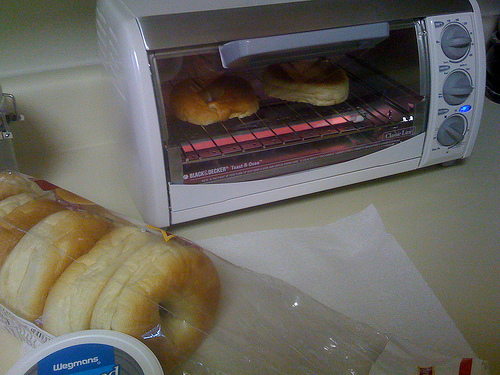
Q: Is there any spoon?
A: No, there are no spoons.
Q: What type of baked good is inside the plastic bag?
A: The food is a bagel.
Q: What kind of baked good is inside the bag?
A: The food is a bagel.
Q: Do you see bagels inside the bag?
A: Yes, there is a bagel inside the bag.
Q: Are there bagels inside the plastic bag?
A: Yes, there is a bagel inside the bag.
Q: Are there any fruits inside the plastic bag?
A: No, there is a bagel inside the bag.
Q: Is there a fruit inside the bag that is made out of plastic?
A: No, there is a bagel inside the bag.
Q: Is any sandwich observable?
A: No, there are no sandwiches.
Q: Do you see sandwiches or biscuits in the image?
A: No, there are no sandwiches or biscuits.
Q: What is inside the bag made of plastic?
A: The bagel is inside the bag.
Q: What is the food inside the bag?
A: The food is a bagel.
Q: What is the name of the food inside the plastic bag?
A: The food is a bagel.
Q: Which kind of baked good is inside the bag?
A: The food is a bagel.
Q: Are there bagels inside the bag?
A: Yes, there is a bagel inside the bag.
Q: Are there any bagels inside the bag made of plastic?
A: Yes, there is a bagel inside the bag.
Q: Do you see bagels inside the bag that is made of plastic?
A: Yes, there is a bagel inside the bag.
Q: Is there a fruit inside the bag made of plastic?
A: No, there is a bagel inside the bag.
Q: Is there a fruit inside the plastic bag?
A: No, there is a bagel inside the bag.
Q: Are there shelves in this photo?
A: No, there are no shelves.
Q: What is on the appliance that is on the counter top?
A: The label is on the toaster oven.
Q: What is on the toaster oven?
A: The label is on the toaster oven.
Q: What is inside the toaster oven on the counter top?
A: The bagel is inside the toaster oven.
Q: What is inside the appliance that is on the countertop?
A: The bagel is inside the toaster oven.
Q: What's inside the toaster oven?
A: The bagel is inside the toaster oven.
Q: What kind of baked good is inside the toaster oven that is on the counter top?
A: The food is a bagel.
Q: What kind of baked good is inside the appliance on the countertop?
A: The food is a bagel.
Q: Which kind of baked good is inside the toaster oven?
A: The food is a bagel.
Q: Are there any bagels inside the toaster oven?
A: Yes, there is a bagel inside the toaster oven.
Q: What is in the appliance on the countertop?
A: The bagel is in the toaster oven.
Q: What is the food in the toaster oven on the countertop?
A: The food is a bagel.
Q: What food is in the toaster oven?
A: The food is a bagel.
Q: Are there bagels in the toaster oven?
A: Yes, there is a bagel in the toaster oven.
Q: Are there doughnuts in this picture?
A: No, there are no doughnuts.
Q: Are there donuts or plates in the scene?
A: No, there are no donuts or plates.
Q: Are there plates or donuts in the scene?
A: No, there are no donuts or plates.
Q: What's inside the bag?
A: The bagel is inside the bag.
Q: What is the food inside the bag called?
A: The food is a bagel.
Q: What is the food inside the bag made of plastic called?
A: The food is a bagel.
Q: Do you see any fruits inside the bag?
A: No, there is a bagel inside the bag.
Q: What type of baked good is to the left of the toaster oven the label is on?
A: The food is a bagel.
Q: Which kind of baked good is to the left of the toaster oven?
A: The food is a bagel.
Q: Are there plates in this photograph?
A: No, there are no plates.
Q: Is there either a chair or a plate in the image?
A: No, there are no plates or chairs.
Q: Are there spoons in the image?
A: No, there are no spoons.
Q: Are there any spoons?
A: No, there are no spoons.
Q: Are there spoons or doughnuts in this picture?
A: No, there are no spoons or doughnuts.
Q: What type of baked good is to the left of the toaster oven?
A: The food is a bagel.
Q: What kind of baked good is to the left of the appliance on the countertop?
A: The food is a bagel.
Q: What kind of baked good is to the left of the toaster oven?
A: The food is a bagel.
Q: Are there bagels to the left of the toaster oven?
A: Yes, there is a bagel to the left of the toaster oven.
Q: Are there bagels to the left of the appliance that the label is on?
A: Yes, there is a bagel to the left of the toaster oven.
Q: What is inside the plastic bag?
A: The bagel is inside the bag.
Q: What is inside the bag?
A: The bagel is inside the bag.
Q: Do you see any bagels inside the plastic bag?
A: Yes, there is a bagel inside the bag.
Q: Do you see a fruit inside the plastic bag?
A: No, there is a bagel inside the bag.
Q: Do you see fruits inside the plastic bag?
A: No, there is a bagel inside the bag.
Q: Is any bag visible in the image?
A: Yes, there is a bag.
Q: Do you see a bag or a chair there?
A: Yes, there is a bag.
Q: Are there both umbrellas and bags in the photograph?
A: No, there is a bag but no umbrellas.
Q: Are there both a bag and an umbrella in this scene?
A: No, there is a bag but no umbrellas.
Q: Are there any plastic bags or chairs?
A: Yes, there is a plastic bag.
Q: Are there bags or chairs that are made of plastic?
A: Yes, the bag is made of plastic.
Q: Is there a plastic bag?
A: Yes, there is a bag that is made of plastic.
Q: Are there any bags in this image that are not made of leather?
A: Yes, there is a bag that is made of plastic.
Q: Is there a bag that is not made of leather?
A: Yes, there is a bag that is made of plastic.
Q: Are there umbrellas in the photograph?
A: No, there are no umbrellas.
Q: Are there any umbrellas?
A: No, there are no umbrellas.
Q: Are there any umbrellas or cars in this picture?
A: No, there are no umbrellas or cars.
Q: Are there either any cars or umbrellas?
A: No, there are no umbrellas or cars.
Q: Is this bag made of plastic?
A: Yes, the bag is made of plastic.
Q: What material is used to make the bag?
A: The bag is made of plastic.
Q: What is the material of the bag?
A: The bag is made of plastic.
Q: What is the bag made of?
A: The bag is made of plastic.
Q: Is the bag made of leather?
A: No, the bag is made of plastic.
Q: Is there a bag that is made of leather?
A: No, there is a bag but it is made of plastic.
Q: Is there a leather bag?
A: No, there is a bag but it is made of plastic.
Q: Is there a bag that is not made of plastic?
A: No, there is a bag but it is made of plastic.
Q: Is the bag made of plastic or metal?
A: The bag is made of plastic.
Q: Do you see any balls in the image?
A: No, there are no balls.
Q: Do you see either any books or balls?
A: No, there are no balls or books.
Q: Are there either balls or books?
A: No, there are no balls or books.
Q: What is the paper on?
A: The paper is on the counter top.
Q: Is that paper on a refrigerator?
A: No, the paper is on the countertop.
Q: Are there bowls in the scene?
A: No, there are no bowls.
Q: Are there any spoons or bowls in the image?
A: No, there are no bowls or spoons.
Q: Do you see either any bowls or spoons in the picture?
A: No, there are no bowls or spoons.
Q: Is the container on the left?
A: Yes, the container is on the left of the image.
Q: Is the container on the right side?
A: No, the container is on the left of the image.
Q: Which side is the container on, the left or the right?
A: The container is on the left of the image.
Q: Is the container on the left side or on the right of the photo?
A: The container is on the left of the image.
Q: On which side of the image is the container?
A: The container is on the left of the image.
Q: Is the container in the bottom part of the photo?
A: Yes, the container is in the bottom of the image.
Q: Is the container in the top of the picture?
A: No, the container is in the bottom of the image.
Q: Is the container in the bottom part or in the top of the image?
A: The container is in the bottom of the image.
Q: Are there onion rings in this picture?
A: No, there are no onion rings.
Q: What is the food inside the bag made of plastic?
A: The food is a bagel.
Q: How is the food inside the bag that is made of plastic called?
A: The food is a bagel.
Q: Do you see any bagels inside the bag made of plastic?
A: Yes, there is a bagel inside the bag.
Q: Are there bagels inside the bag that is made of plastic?
A: Yes, there is a bagel inside the bag.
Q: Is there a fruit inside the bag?
A: No, there is a bagel inside the bag.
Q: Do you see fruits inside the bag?
A: No, there is a bagel inside the bag.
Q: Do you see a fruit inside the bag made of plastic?
A: No, there is a bagel inside the bag.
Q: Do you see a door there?
A: Yes, there is a door.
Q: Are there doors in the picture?
A: Yes, there is a door.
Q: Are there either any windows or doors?
A: Yes, there is a door.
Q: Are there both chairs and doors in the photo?
A: No, there is a door but no chairs.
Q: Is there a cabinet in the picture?
A: No, there are no cabinets.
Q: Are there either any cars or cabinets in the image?
A: No, there are no cabinets or cars.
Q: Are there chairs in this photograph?
A: No, there are no chairs.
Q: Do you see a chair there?
A: No, there are no chairs.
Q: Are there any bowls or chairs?
A: No, there are no chairs or bowls.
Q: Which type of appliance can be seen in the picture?
A: The appliance is a toaster oven.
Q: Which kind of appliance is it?
A: The appliance is a toaster oven.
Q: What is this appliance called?
A: This is a toaster oven.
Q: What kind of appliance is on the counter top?
A: The appliance is a toaster oven.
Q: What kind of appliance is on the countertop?
A: The appliance is a toaster oven.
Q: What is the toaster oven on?
A: The toaster oven is on the countertop.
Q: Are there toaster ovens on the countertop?
A: Yes, there is a toaster oven on the countertop.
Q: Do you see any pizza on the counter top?
A: No, there is a toaster oven on the counter top.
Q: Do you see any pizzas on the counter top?
A: No, there is a toaster oven on the counter top.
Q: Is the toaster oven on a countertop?
A: Yes, the toaster oven is on a countertop.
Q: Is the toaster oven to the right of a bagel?
A: Yes, the toaster oven is to the right of a bagel.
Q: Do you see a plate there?
A: No, there are no plates.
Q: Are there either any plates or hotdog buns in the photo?
A: No, there are no plates or hotdog buns.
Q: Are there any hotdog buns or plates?
A: No, there are no plates or hotdog buns.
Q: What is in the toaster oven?
A: The bagel is in the toaster oven.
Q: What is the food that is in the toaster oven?
A: The food is a bagel.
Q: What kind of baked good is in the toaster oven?
A: The food is a bagel.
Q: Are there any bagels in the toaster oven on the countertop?
A: Yes, there is a bagel in the toaster oven.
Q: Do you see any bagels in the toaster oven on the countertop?
A: Yes, there is a bagel in the toaster oven.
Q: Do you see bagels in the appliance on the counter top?
A: Yes, there is a bagel in the toaster oven.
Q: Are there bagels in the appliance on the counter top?
A: Yes, there is a bagel in the toaster oven.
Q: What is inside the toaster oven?
A: The bagel is inside the toaster oven.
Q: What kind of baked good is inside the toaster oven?
A: The food is a bagel.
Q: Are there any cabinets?
A: No, there are no cabinets.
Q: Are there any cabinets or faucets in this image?
A: No, there are no cabinets or faucets.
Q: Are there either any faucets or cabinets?
A: No, there are no cabinets or faucets.